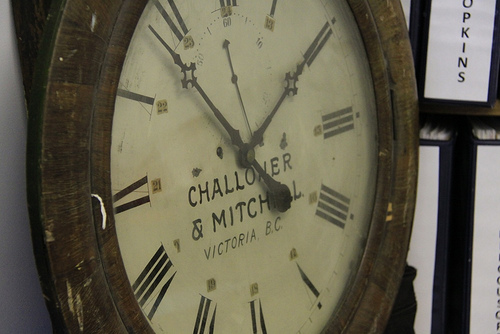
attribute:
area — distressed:
[49, 176, 102, 319]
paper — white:
[413, 5, 497, 96]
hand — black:
[236, 40, 317, 161]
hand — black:
[148, 23, 293, 214]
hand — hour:
[248, 44, 319, 149]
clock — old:
[119, 22, 336, 262]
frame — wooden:
[329, 25, 441, 260]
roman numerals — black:
[315, 170, 358, 245]